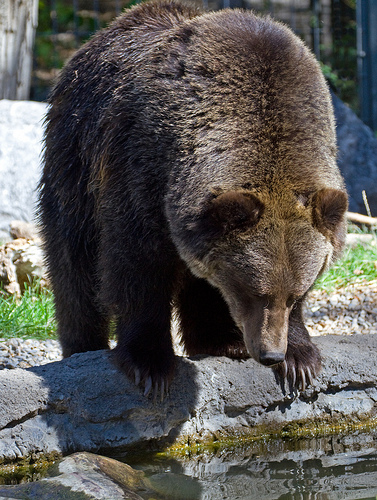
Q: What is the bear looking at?
A: Water.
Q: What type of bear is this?
A: Black bear.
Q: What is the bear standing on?
A: Rock.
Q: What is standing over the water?
A: Bear.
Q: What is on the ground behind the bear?
A: Grass.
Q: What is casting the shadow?
A: Bear.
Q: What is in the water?
A: Reflection.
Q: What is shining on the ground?
A: Sunlight.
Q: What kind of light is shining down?
A: Sunlight.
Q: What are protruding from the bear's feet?
A: Claws.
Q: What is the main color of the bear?
A: Brown.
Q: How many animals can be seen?
A: One.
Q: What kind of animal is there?
A: A bear.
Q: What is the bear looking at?
A: Water.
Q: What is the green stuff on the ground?
A: Grass.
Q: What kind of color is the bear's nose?
A: Black.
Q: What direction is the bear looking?
A: Down.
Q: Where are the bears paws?
A: Concrete bank.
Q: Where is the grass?
A: Behind bear.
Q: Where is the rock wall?
A: Behind grass.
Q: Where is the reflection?
A: In water.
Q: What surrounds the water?
A: Concrete.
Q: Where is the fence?
A: Behind rock wall.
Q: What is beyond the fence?
A: Trees.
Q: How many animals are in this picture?
A: One.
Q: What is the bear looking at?
A: The water.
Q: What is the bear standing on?
A: Stone edge of a body of water.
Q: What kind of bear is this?
A: Brown bear.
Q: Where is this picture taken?
A: The forest.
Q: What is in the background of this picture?
A: Rock and foliage.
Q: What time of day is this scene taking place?
A: Daytime.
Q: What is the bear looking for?
A: Fish and water.